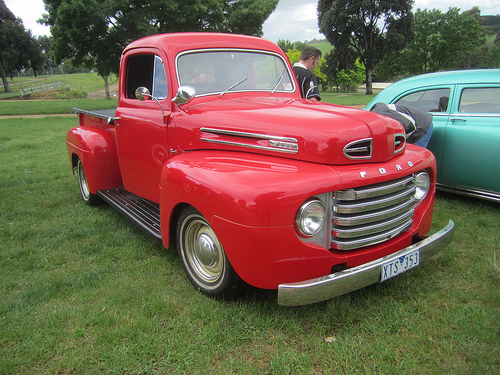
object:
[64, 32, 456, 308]
silver ford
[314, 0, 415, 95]
green trees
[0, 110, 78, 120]
tan trail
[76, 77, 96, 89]
grass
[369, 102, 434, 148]
person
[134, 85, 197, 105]
double mirrors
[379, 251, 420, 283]
license plate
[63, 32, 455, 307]
pickup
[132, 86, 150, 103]
mirror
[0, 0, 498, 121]
scene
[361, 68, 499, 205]
car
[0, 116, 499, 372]
field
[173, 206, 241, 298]
tire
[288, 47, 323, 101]
man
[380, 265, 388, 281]
letters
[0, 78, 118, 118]
road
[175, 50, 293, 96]
windshield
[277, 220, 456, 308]
bumper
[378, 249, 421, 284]
plate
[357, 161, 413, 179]
ford sign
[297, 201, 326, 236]
headlight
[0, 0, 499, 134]
background